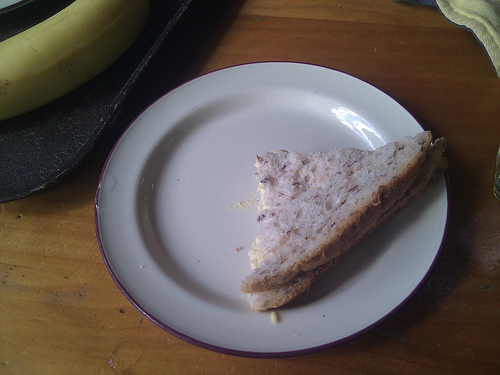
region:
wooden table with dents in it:
[3, 203, 90, 369]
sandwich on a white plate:
[243, 131, 445, 306]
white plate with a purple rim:
[113, 132, 243, 297]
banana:
[1, 0, 121, 110]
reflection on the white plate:
[331, 103, 380, 145]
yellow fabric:
[435, 1, 499, 76]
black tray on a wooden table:
[2, 120, 69, 179]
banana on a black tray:
[1, 13, 119, 124]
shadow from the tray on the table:
[193, 11, 231, 62]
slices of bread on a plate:
[249, 134, 444, 309]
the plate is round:
[133, 112, 379, 314]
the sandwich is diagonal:
[237, 137, 461, 310]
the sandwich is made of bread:
[242, 165, 494, 342]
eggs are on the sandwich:
[196, 135, 346, 344]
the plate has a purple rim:
[82, 178, 191, 352]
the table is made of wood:
[34, 268, 91, 348]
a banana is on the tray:
[17, 33, 164, 155]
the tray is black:
[48, 121, 139, 206]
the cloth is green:
[425, 25, 498, 58]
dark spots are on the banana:
[39, 46, 137, 74]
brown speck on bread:
[259, 171, 271, 187]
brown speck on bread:
[256, 209, 268, 231]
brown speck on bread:
[271, 229, 299, 243]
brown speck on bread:
[289, 179, 307, 194]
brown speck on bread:
[300, 156, 310, 167]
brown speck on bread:
[325, 163, 351, 185]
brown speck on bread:
[349, 183, 370, 210]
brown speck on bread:
[342, 163, 370, 180]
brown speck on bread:
[376, 138, 397, 165]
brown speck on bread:
[386, 149, 406, 167]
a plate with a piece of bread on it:
[92, 83, 414, 365]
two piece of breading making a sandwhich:
[245, 153, 390, 300]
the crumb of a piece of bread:
[272, 305, 283, 337]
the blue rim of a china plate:
[91, 235, 133, 285]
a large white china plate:
[138, 62, 412, 363]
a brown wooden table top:
[10, 273, 92, 337]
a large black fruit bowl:
[20, 109, 77, 220]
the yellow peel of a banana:
[7, 26, 89, 101]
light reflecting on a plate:
[300, 72, 370, 132]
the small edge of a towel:
[420, 3, 492, 35]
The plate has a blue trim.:
[85, 202, 120, 247]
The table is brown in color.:
[13, 307, 108, 362]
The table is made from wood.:
[7, 302, 82, 367]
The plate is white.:
[96, 207, 224, 253]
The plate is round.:
[90, 52, 452, 356]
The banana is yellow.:
[21, 27, 66, 76]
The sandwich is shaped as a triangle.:
[234, 138, 449, 295]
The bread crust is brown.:
[336, 235, 356, 248]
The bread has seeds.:
[280, 176, 327, 201]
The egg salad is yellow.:
[250, 170, 269, 205]